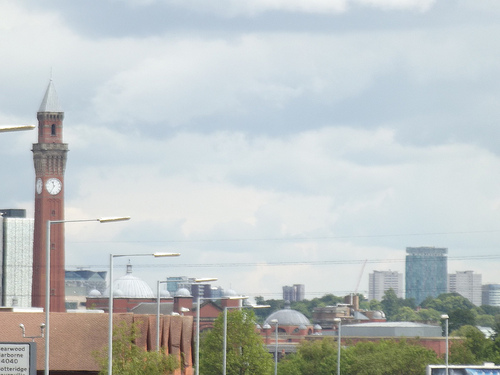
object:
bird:
[0, 125, 36, 135]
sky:
[0, 2, 500, 297]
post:
[44, 222, 51, 375]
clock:
[45, 177, 62, 195]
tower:
[29, 68, 69, 313]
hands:
[48, 180, 61, 195]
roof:
[103, 263, 156, 298]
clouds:
[0, 0, 500, 303]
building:
[261, 309, 323, 347]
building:
[405, 245, 450, 304]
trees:
[94, 288, 499, 375]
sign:
[1, 344, 30, 374]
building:
[0, 208, 44, 314]